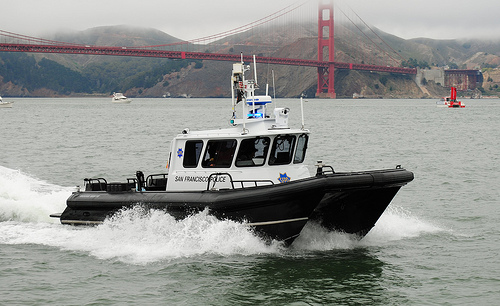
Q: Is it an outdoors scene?
A: Yes, it is outdoors.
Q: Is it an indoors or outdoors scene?
A: It is outdoors.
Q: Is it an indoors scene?
A: No, it is outdoors.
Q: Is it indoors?
A: No, it is outdoors.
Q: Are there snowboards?
A: No, there are no snowboards.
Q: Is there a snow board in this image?
A: No, there are no snowboards.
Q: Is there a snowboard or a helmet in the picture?
A: No, there are no snowboards or helmets.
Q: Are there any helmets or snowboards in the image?
A: No, there are no snowboards or helmets.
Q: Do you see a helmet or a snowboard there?
A: No, there are no snowboards or helmets.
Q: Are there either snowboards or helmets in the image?
A: No, there are no snowboards or helmets.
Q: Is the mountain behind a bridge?
A: Yes, the mountain is behind a bridge.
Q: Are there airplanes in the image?
A: No, there are no airplanes.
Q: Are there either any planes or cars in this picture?
A: No, there are no planes or cars.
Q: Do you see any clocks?
A: No, there are no clocks.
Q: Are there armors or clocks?
A: No, there are no clocks or armors.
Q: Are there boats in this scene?
A: Yes, there is a boat.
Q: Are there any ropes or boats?
A: Yes, there is a boat.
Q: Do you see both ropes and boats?
A: No, there is a boat but no ropes.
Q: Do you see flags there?
A: No, there are no flags.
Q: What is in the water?
A: The boat is in the water.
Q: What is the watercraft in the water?
A: The watercraft is a boat.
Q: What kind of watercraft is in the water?
A: The watercraft is a boat.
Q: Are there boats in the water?
A: Yes, there is a boat in the water.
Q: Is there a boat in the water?
A: Yes, there is a boat in the water.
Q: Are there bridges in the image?
A: Yes, there is a bridge.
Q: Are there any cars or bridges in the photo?
A: Yes, there is a bridge.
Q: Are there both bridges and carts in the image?
A: No, there is a bridge but no carts.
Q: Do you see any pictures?
A: No, there are no pictures.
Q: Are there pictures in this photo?
A: No, there are no pictures.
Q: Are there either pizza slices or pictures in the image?
A: No, there are no pictures or pizza slices.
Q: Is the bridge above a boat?
A: Yes, the bridge is above a boat.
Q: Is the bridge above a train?
A: No, the bridge is above a boat.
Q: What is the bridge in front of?
A: The bridge is in front of the mountain.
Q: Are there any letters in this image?
A: Yes, there are letters.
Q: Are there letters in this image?
A: Yes, there are letters.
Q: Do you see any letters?
A: Yes, there are letters.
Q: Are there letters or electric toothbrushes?
A: Yes, there are letters.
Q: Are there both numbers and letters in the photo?
A: No, there are letters but no numbers.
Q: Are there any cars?
A: No, there are no cars.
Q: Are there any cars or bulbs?
A: No, there are no cars or bulbs.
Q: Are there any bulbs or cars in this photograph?
A: No, there are no cars or bulbs.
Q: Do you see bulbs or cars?
A: No, there are no cars or bulbs.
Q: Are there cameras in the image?
A: Yes, there is a camera.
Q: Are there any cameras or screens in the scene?
A: Yes, there is a camera.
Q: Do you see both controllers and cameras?
A: No, there is a camera but no controllers.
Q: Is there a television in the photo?
A: No, there are no televisions.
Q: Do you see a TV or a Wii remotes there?
A: No, there are no televisions or Wii controllers.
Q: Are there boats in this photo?
A: Yes, there is a boat.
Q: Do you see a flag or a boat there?
A: Yes, there is a boat.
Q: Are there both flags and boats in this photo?
A: No, there is a boat but no flags.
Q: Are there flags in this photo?
A: No, there are no flags.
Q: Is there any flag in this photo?
A: No, there are no flags.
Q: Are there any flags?
A: No, there are no flags.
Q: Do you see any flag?
A: No, there are no flags.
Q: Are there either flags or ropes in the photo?
A: No, there are no flags or ropes.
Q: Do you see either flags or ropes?
A: No, there are no flags or ropes.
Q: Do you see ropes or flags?
A: No, there are no flags or ropes.